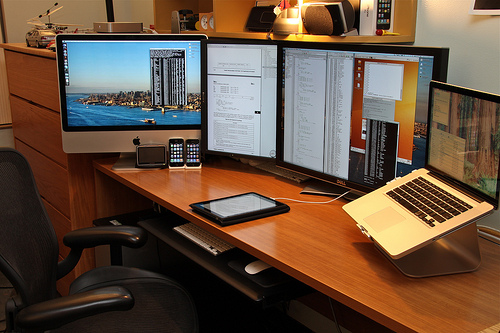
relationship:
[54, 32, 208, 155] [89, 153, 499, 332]
monitor on desk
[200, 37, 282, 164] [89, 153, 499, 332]
monitor on desk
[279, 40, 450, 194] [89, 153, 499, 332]
monitor on desk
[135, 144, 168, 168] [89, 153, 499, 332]
smartphone on desk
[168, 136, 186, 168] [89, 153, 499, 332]
smartphone on desk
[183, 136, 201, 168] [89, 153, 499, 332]
smartphone on desk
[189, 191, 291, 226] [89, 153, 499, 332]
tablet on desk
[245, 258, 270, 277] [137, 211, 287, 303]
mouse on drawer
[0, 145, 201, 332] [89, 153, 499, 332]
chair near desk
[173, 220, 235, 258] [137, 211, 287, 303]
keyboard on drawer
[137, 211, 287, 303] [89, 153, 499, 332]
drawer attached to desk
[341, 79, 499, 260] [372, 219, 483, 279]
laptop on stand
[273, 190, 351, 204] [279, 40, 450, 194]
cord attached to monitor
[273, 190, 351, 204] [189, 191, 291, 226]
cord attached to tablet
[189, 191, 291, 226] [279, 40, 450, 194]
tablet attached to monitor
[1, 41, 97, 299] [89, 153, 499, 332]
file cabinet next to desk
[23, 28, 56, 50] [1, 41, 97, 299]
car on file cabinet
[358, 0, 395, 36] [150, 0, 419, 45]
phone box on shelf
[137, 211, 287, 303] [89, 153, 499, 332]
drawer under desk